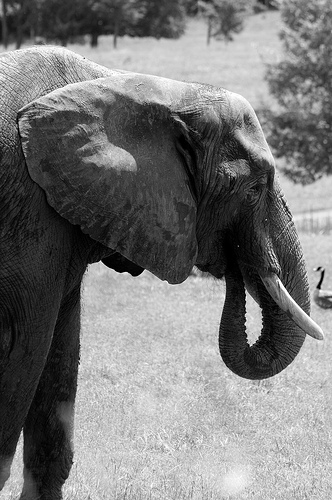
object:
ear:
[15, 72, 198, 285]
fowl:
[313, 265, 332, 310]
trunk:
[217, 181, 312, 382]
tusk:
[256, 266, 323, 343]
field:
[0, 0, 332, 500]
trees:
[0, 1, 330, 204]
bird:
[313, 266, 332, 313]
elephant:
[0, 36, 324, 500]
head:
[14, 68, 327, 382]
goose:
[312, 264, 332, 311]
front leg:
[0, 241, 63, 496]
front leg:
[18, 280, 81, 497]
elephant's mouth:
[219, 216, 245, 276]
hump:
[0, 43, 91, 103]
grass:
[0, 0, 332, 500]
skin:
[64, 120, 175, 223]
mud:
[155, 199, 199, 263]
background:
[0, 0, 332, 292]